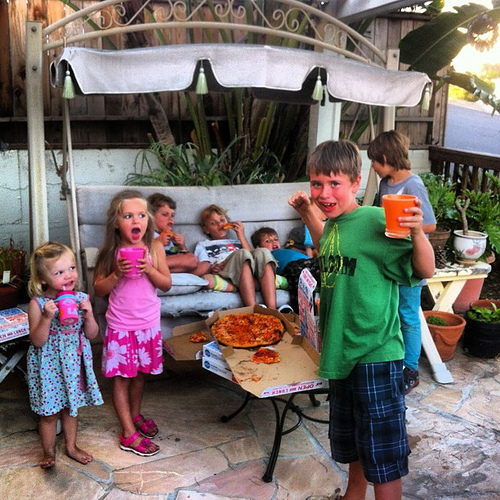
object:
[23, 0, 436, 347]
metal bench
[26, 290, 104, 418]
dress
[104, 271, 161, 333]
pink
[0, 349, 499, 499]
ground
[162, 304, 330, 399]
box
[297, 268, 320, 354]
box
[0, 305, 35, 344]
box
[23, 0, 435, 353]
swing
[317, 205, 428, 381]
shirt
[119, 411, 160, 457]
sandles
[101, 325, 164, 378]
shorts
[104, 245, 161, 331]
shirt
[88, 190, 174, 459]
child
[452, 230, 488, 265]
flower pot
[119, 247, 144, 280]
cup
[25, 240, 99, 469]
child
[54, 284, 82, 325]
cup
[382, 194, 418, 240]
cup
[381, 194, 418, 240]
orange glass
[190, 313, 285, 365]
pizza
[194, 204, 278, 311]
boy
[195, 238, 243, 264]
shirt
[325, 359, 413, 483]
shorts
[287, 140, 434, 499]
boy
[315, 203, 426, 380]
tee shirt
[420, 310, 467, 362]
flower pot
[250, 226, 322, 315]
boy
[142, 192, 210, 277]
boy